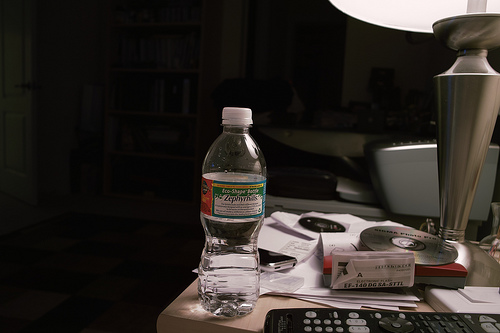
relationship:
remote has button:
[265, 305, 498, 331] [342, 314, 371, 326]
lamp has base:
[325, 2, 500, 283] [427, 14, 500, 295]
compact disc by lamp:
[356, 221, 466, 271] [325, 2, 500, 283]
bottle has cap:
[195, 96, 269, 323] [218, 106, 252, 127]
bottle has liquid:
[195, 96, 269, 323] [197, 212, 259, 316]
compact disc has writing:
[356, 221, 466, 271] [369, 226, 441, 243]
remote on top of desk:
[265, 305, 498, 331] [155, 166, 498, 330]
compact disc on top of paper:
[356, 221, 466, 271] [316, 224, 467, 284]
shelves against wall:
[98, 1, 220, 211] [33, 8, 500, 227]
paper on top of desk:
[316, 224, 467, 284] [155, 166, 498, 330]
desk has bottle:
[155, 166, 498, 330] [195, 96, 269, 323]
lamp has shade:
[325, 2, 500, 283] [327, 0, 500, 29]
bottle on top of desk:
[195, 96, 269, 323] [155, 166, 498, 330]